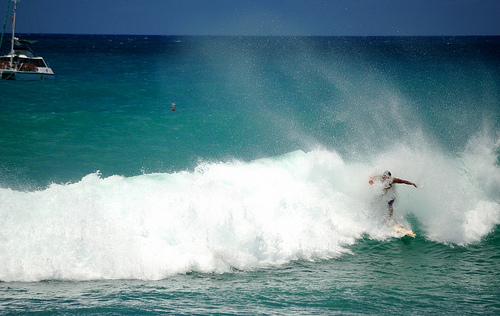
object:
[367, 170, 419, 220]
surfer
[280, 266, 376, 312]
water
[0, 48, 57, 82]
boat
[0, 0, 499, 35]
sky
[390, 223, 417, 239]
board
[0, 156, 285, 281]
wave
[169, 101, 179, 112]
buoy